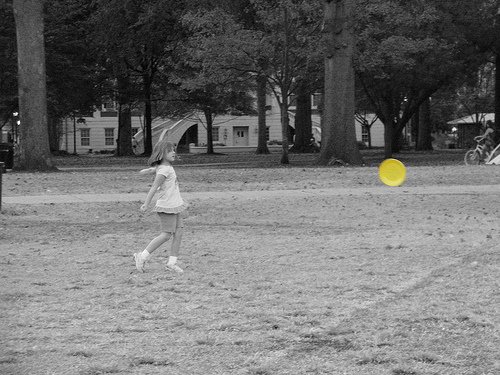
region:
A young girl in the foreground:
[122, 128, 206, 283]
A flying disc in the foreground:
[370, 143, 421, 202]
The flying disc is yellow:
[366, 145, 413, 192]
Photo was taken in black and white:
[4, 3, 499, 371]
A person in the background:
[450, 114, 499, 166]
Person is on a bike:
[461, 112, 499, 169]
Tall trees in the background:
[2, 2, 497, 177]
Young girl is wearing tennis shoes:
[116, 244, 196, 282]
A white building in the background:
[1, 10, 413, 162]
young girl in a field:
[126, 138, 196, 278]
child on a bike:
[461, 113, 498, 165]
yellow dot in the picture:
[377, 151, 406, 190]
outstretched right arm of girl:
[131, 165, 171, 218]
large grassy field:
[2, 149, 498, 374]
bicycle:
[463, 139, 496, 166]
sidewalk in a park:
[2, 182, 499, 205]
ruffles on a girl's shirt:
[152, 198, 192, 219]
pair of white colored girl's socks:
[134, 248, 179, 265]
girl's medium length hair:
[145, 137, 176, 164]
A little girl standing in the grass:
[131, 138, 188, 275]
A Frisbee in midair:
[378, 157, 408, 187]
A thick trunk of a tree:
[308, 52, 367, 167]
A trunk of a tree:
[10, 3, 55, 171]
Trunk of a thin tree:
[205, 117, 214, 158]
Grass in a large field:
[15, 210, 492, 373]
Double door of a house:
[233, 126, 248, 145]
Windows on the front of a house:
[77, 125, 117, 150]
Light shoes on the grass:
[131, 247, 184, 276]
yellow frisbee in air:
[375, 144, 411, 204]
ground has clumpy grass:
[268, 270, 404, 355]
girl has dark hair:
[124, 120, 183, 170]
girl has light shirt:
[156, 167, 209, 224]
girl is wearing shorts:
[163, 215, 179, 231]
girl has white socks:
[129, 250, 195, 285]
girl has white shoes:
[130, 251, 182, 271]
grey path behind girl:
[219, 168, 334, 203]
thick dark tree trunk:
[319, 57, 365, 182]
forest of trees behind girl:
[18, 0, 443, 100]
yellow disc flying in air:
[358, 155, 430, 201]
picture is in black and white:
[29, 63, 494, 353]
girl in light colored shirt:
[148, 178, 187, 215]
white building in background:
[61, 118, 158, 160]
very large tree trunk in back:
[28, 104, 50, 134]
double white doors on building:
[218, 120, 274, 162]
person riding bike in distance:
[454, 131, 498, 174]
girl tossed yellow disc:
[128, 138, 226, 290]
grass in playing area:
[253, 310, 311, 325]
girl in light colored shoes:
[125, 243, 239, 302]